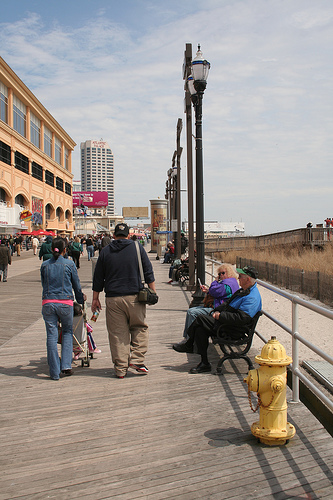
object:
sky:
[0, 0, 332, 236]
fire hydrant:
[245, 335, 297, 446]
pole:
[195, 79, 204, 291]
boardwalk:
[0, 246, 332, 499]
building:
[81, 140, 114, 217]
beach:
[206, 223, 333, 310]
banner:
[73, 190, 108, 208]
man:
[172, 264, 262, 373]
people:
[0, 238, 11, 282]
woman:
[39, 238, 86, 380]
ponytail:
[55, 246, 61, 259]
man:
[89, 224, 155, 376]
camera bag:
[139, 288, 160, 304]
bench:
[212, 310, 263, 376]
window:
[44, 123, 53, 159]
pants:
[191, 310, 256, 356]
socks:
[186, 333, 194, 347]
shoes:
[190, 361, 212, 373]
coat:
[211, 285, 261, 337]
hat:
[237, 261, 256, 277]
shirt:
[91, 236, 155, 297]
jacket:
[41, 256, 83, 305]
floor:
[0, 250, 332, 499]